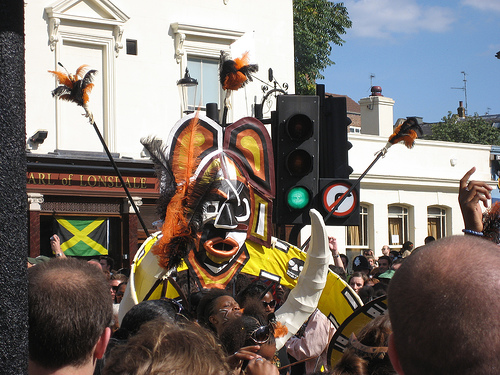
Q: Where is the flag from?
A: Jamaica.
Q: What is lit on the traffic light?
A: Green light.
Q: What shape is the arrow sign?
A: Circle.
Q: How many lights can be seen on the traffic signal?
A: Three.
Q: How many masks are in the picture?
A: One.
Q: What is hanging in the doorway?
A: Flag.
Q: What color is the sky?
A: Blue.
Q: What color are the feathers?
A: Orange & black.